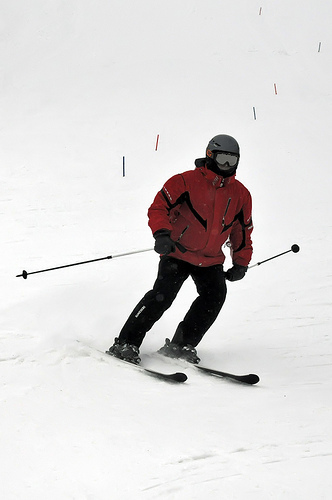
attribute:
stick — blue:
[120, 155, 128, 179]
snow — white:
[1, 4, 331, 500]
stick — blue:
[251, 104, 258, 120]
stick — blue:
[317, 39, 323, 57]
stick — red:
[153, 132, 161, 151]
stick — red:
[271, 82, 279, 98]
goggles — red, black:
[213, 149, 241, 168]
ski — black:
[141, 347, 261, 386]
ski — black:
[56, 336, 188, 388]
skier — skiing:
[111, 135, 251, 367]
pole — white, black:
[15, 245, 170, 278]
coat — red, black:
[147, 168, 254, 267]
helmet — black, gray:
[205, 134, 243, 159]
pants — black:
[116, 254, 227, 347]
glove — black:
[153, 235, 176, 254]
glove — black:
[225, 263, 248, 281]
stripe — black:
[166, 189, 205, 228]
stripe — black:
[222, 209, 246, 250]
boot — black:
[109, 341, 142, 364]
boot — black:
[160, 336, 199, 364]